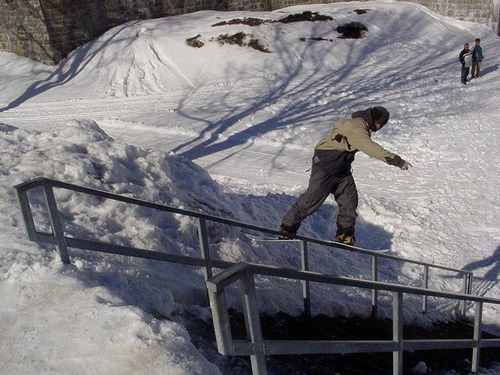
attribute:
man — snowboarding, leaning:
[279, 106, 414, 246]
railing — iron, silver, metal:
[13, 177, 499, 375]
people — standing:
[460, 39, 485, 85]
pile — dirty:
[0, 117, 342, 270]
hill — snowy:
[52, 0, 487, 87]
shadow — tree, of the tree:
[169, 8, 499, 167]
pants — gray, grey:
[281, 167, 357, 233]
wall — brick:
[1, 0, 499, 65]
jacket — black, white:
[460, 48, 474, 71]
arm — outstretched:
[353, 131, 413, 172]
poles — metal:
[41, 183, 483, 374]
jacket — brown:
[314, 119, 405, 179]